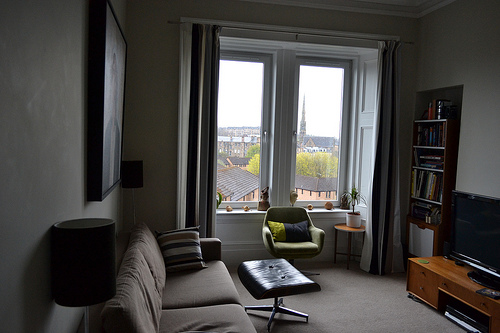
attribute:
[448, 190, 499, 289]
television — black, flat screen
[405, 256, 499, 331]
entertainment consol — brown, wood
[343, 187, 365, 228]
plant — potted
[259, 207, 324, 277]
chair — green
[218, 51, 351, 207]
window — opened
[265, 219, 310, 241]
pillow — green, black, blue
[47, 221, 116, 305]
lamp shade — black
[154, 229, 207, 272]
pillow — striped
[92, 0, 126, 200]
painting — hanging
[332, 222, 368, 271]
table — round, small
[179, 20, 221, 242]
curtain — striped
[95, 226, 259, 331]
sofa — brown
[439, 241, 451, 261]
speaker — small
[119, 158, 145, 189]
lamp shade — round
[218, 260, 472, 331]
floor — carpet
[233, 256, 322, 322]
seat — leather